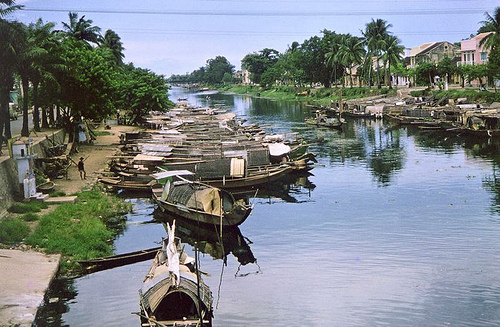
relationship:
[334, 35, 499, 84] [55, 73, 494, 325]
houses overlook water canal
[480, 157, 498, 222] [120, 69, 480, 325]
reflection on water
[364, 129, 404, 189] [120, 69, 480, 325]
reflection on water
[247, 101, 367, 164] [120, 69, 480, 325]
reflection on water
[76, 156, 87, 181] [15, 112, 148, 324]
man on river bank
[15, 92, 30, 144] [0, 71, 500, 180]
trunk behind ground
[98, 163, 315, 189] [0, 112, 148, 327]
boat near river bank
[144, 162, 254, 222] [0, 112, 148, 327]
boats near river bank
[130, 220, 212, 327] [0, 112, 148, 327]
boat near river bank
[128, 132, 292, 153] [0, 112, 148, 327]
boat near river bank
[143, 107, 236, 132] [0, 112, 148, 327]
boats near river bank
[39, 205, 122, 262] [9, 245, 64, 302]
grass on shore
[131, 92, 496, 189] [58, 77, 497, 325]
boats on water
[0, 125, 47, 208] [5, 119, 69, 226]
ojects leaning by wall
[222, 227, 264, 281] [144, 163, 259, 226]
reflection of boat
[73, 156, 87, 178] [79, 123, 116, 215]
man walking along dock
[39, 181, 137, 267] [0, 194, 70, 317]
grass growing on dock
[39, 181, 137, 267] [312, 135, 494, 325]
grass growing on water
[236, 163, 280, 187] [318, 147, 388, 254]
boat docked in water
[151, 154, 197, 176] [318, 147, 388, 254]
boat docked in water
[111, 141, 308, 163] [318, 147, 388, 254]
boat docked in water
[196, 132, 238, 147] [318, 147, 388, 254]
boat docked in water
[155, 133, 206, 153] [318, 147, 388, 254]
boat docked in water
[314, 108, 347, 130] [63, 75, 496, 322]
boat sailing on river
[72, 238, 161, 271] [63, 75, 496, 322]
canoe docked on river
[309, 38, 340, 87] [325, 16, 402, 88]
leaves on palm trees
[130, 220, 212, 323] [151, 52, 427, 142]
boat in foreground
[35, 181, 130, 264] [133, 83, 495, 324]
greens in between water